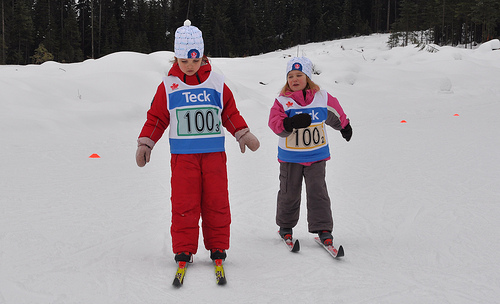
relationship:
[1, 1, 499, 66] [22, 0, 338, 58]
trees in background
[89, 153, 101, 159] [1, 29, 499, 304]
safety cone on ground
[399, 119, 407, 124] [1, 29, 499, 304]
safety cone on ground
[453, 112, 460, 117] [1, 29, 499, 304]
safety cone on ground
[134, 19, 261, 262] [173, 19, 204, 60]
child wearing hat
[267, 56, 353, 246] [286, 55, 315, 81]
child wearing hat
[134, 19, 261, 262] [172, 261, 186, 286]
child wearing ski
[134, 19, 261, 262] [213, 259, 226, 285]
child wearing ski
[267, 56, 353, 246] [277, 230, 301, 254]
child wearing ski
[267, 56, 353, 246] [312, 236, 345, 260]
child wearing ski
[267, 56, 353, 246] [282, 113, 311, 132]
child wearing mitten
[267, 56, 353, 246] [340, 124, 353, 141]
child wearing mitten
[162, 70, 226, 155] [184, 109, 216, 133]
vest shows number 100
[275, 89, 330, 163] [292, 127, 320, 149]
vest shows number 100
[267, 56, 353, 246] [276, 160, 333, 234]
child wears ski pants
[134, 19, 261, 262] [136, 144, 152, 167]
child wears mitten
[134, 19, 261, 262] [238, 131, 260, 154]
child wears mitten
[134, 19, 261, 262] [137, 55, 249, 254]
child wearing ski suit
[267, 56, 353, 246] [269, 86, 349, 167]
child wearing coat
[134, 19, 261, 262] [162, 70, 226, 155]
child wearing vest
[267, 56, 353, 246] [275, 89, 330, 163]
child wearing vest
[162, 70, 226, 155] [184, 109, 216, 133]
vest displays number 100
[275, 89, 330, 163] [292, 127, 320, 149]
vest displays number 100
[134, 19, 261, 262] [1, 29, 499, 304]
child looking at ground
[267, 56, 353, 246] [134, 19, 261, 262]
child looking at child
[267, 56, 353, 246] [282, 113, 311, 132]
child wears mitten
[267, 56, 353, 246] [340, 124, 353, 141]
child wears mitten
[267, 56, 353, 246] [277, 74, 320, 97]
child has hair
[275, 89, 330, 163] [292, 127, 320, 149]
vest has number 100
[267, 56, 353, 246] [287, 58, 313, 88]
child has head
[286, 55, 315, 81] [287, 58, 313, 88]
hat on head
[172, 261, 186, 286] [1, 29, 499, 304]
ski gliding on ground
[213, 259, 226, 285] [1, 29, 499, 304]
ski gliding on ground